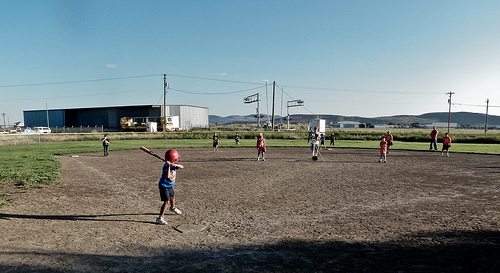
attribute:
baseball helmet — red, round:
[163, 151, 178, 164]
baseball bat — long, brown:
[140, 145, 186, 170]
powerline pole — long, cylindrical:
[157, 68, 172, 125]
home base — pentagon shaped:
[167, 213, 217, 237]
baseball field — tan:
[183, 141, 459, 270]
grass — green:
[3, 155, 57, 195]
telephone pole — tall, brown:
[439, 84, 460, 146]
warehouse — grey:
[20, 99, 212, 139]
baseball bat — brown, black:
[133, 139, 170, 171]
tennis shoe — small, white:
[151, 210, 170, 229]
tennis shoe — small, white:
[165, 202, 185, 221]